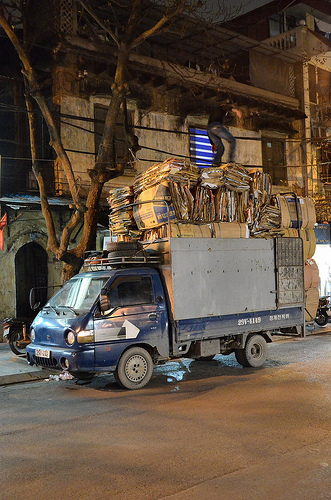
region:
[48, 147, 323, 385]
this is a pick up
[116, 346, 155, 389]
this is a wheel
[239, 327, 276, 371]
this is a wheel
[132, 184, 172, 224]
this is a carton on the pick up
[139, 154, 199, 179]
this is a carton on the pick up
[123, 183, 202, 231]
this is a carton on the pick up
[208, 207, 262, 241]
this is a carton on the pick up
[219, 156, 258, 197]
this is a carton on the pick up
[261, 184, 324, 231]
this is a carton on the pick up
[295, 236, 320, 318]
this is a carton on the pick up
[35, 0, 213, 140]
the tree is bare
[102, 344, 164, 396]
the wheel is black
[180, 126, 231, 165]
the window is blue and white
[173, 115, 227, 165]
the window is striped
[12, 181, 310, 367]
the truck is parked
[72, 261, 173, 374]
the door is closed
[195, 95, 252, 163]
the man is in motion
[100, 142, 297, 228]
tied up cardboard boxes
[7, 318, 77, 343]
the headlights are off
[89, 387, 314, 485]
the street is grey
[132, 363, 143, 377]
part f a rim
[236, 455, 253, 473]
aprt of a ine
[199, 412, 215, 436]
aprt of a shade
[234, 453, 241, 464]
par tof a road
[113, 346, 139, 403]
edge of a whek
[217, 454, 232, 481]
part fo a line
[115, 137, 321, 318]
card board inside of a truck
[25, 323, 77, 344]
head lights on a truck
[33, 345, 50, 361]
license plate on a truck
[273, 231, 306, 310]
door open on a truck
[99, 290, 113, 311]
mirror on a truck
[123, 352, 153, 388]
silver rims on a truck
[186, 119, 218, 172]
window on a buildng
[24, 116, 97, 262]
tree with no leaves on it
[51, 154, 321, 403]
card board inside of a truck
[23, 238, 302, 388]
a blue truck with a gray colored bed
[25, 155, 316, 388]
a blue truck loaded with compacted boxes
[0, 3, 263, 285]
a large dead tree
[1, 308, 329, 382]
a gray colored concrete sidewalk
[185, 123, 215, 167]
blue and white stripes on the building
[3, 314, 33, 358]
a parked dark colored motorcycle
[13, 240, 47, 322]
a arched doorway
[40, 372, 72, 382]
litter against the curb beside the truck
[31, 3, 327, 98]
balconies on the front of the rock building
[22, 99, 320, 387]
a person standing on top of the boxes on the back of the truck